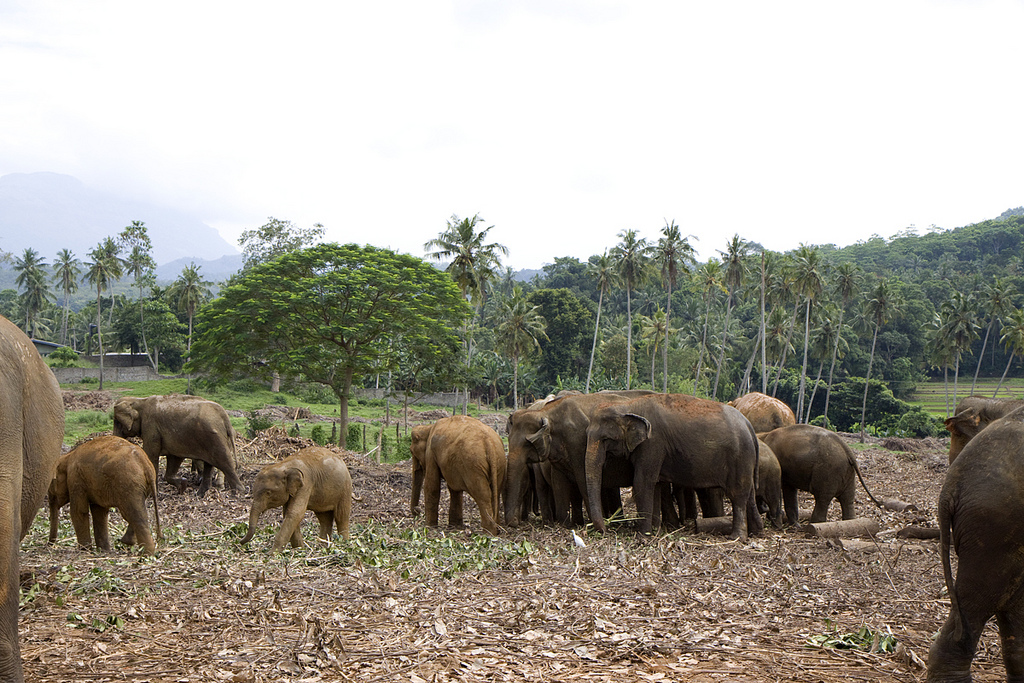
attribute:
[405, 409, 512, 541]
elephant — reddish brown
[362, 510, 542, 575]
grass — tall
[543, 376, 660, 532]
trunk — brown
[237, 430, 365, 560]
elephant — small